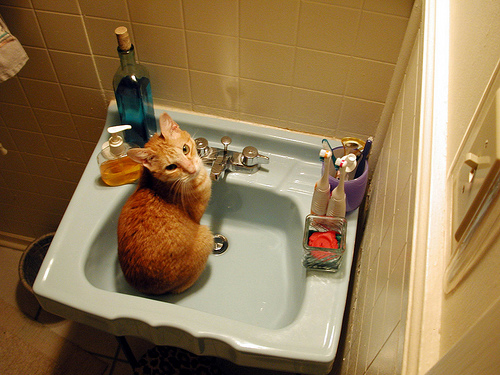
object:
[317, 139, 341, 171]
brush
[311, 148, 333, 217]
brush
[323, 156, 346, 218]
brush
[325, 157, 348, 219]
holder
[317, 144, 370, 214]
purple cup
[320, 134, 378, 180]
toiletries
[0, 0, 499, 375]
bathroom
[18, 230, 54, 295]
basket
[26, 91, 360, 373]
bathroom sink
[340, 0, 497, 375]
wall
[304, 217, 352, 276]
candle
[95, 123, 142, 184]
liquid soap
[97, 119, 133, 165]
soap dispenser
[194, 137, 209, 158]
knob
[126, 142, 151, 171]
ear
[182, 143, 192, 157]
eyes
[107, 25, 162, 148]
bottle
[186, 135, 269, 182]
faucet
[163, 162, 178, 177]
eye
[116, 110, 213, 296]
cat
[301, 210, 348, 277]
candle holder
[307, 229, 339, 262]
candle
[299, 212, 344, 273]
holder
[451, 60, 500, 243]
light switch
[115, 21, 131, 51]
cork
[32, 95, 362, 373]
sink ledge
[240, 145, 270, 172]
knob